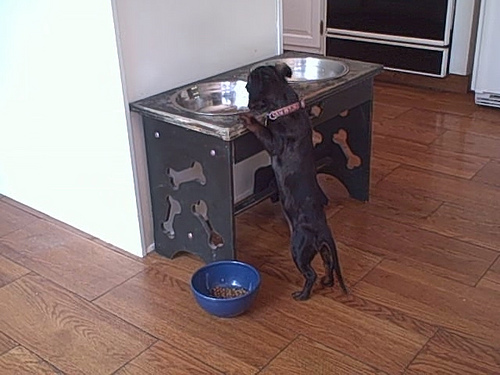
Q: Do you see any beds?
A: No, there are no beds.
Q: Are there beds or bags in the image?
A: No, there are no beds or bags.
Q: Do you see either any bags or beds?
A: No, there are no beds or bags.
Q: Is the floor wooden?
A: Yes, the floor is wooden.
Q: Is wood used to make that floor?
A: Yes, the floor is made of wood.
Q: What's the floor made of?
A: The floor is made of wood.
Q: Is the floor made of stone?
A: No, the floor is made of wood.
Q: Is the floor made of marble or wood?
A: The floor is made of wood.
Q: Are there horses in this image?
A: No, there are no horses.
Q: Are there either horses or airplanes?
A: No, there are no horses or airplanes.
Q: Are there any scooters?
A: No, there are no scooters.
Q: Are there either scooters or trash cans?
A: No, there are no scooters or trash cans.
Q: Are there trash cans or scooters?
A: No, there are no scooters or trash cans.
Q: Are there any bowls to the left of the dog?
A: Yes, there is a bowl to the left of the dog.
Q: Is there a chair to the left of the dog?
A: No, there is a bowl to the left of the dog.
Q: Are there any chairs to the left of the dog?
A: No, there is a bowl to the left of the dog.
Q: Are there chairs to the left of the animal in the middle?
A: No, there is a bowl to the left of the dog.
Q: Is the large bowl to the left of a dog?
A: Yes, the bowl is to the left of a dog.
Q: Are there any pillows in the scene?
A: No, there are no pillows.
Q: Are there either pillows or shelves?
A: No, there are no pillows or shelves.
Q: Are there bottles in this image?
A: No, there are no bottles.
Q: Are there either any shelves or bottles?
A: No, there are no bottles or shelves.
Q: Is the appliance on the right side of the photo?
A: Yes, the appliance is on the right of the image.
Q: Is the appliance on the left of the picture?
A: No, the appliance is on the right of the image.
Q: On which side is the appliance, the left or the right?
A: The appliance is on the right of the image.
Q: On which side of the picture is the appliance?
A: The appliance is on the right of the image.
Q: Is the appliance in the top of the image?
A: Yes, the appliance is in the top of the image.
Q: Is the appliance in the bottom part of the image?
A: No, the appliance is in the top of the image.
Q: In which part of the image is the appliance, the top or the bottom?
A: The appliance is in the top of the image.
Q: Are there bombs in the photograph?
A: No, there are no bombs.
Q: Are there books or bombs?
A: No, there are no bombs or books.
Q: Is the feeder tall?
A: Yes, the feeder is tall.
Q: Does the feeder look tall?
A: Yes, the feeder is tall.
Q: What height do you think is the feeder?
A: The feeder is tall.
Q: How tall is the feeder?
A: The feeder is tall.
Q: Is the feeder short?
A: No, the feeder is tall.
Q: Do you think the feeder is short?
A: No, the feeder is tall.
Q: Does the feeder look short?
A: No, the feeder is tall.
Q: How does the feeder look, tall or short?
A: The feeder is tall.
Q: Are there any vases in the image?
A: No, there are no vases.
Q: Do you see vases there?
A: No, there are no vases.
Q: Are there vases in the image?
A: No, there are no vases.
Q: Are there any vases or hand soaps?
A: No, there are no vases or hand soaps.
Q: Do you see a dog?
A: Yes, there is a dog.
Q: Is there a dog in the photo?
A: Yes, there is a dog.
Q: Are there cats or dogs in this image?
A: Yes, there is a dog.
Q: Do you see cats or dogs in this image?
A: Yes, there is a dog.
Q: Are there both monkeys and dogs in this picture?
A: No, there is a dog but no monkeys.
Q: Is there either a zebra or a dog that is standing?
A: Yes, the dog is standing.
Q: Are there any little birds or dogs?
A: Yes, there is a little dog.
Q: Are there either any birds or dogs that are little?
A: Yes, the dog is little.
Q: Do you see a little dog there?
A: Yes, there is a little dog.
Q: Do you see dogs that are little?
A: Yes, there is a little dog.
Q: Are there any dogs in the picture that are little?
A: Yes, there is a dog that is little.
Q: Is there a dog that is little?
A: Yes, there is a dog that is little.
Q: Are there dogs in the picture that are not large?
A: Yes, there is a little dog.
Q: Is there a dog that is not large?
A: Yes, there is a little dog.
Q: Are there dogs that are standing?
A: Yes, there is a dog that is standing.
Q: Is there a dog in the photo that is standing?
A: Yes, there is a dog that is standing.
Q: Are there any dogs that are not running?
A: Yes, there is a dog that is standing.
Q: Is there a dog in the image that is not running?
A: Yes, there is a dog that is standing.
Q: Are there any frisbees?
A: No, there are no frisbees.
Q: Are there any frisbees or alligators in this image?
A: No, there are no frisbees or alligators.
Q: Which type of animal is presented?
A: The animal is a dog.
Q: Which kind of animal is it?
A: The animal is a dog.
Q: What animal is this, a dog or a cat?
A: That is a dog.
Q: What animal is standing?
A: The animal is a dog.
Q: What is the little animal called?
A: The animal is a dog.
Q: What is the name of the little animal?
A: The animal is a dog.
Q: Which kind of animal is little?
A: The animal is a dog.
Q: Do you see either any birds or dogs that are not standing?
A: No, there is a dog but it is standing.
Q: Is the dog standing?
A: Yes, the dog is standing.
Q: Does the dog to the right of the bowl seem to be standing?
A: Yes, the dog is standing.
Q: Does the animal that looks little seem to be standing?
A: Yes, the dog is standing.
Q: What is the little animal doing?
A: The dog is standing.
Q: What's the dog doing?
A: The dog is standing.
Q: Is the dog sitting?
A: No, the dog is standing.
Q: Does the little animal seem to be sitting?
A: No, the dog is standing.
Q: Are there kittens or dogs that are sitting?
A: No, there is a dog but it is standing.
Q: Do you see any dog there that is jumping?
A: No, there is a dog but it is standing.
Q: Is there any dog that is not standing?
A: No, there is a dog but it is standing.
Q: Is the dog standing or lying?
A: The dog is standing.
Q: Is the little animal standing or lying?
A: The dog is standing.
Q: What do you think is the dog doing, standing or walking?
A: The dog is standing.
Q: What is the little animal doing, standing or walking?
A: The dog is standing.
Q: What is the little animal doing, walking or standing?
A: The dog is standing.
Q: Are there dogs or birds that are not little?
A: No, there is a dog but it is little.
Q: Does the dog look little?
A: Yes, the dog is little.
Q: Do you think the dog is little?
A: Yes, the dog is little.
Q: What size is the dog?
A: The dog is little.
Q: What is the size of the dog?
A: The dog is little.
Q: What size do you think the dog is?
A: The dog is little.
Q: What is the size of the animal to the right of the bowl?
A: The dog is little.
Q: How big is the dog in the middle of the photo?
A: The dog is little.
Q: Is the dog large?
A: No, the dog is little.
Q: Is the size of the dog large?
A: No, the dog is little.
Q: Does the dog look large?
A: No, the dog is little.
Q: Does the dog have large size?
A: No, the dog is little.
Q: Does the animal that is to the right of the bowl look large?
A: No, the dog is little.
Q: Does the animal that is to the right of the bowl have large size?
A: No, the dog is little.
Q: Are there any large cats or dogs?
A: No, there is a dog but it is little.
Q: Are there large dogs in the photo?
A: No, there is a dog but it is little.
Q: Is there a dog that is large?
A: No, there is a dog but it is little.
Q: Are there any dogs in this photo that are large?
A: No, there is a dog but it is little.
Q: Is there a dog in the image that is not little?
A: No, there is a dog but it is little.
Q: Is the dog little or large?
A: The dog is little.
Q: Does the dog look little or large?
A: The dog is little.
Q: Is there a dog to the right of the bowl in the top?
A: Yes, there is a dog to the right of the bowl.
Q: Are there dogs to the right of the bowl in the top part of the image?
A: Yes, there is a dog to the right of the bowl.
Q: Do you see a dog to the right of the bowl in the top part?
A: Yes, there is a dog to the right of the bowl.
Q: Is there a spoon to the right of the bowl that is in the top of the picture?
A: No, there is a dog to the right of the bowl.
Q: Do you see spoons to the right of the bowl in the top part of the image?
A: No, there is a dog to the right of the bowl.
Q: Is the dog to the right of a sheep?
A: No, the dog is to the right of the bowl.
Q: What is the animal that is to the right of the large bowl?
A: The animal is a dog.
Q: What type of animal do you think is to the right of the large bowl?
A: The animal is a dog.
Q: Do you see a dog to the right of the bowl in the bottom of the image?
A: Yes, there is a dog to the right of the bowl.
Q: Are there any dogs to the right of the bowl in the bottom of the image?
A: Yes, there is a dog to the right of the bowl.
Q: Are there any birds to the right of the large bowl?
A: No, there is a dog to the right of the bowl.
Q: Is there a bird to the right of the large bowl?
A: No, there is a dog to the right of the bowl.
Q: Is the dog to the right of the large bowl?
A: Yes, the dog is to the right of the bowl.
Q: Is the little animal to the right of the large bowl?
A: Yes, the dog is to the right of the bowl.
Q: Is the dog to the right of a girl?
A: No, the dog is to the right of the bowl.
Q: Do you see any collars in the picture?
A: Yes, there is a collar.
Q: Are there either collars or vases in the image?
A: Yes, there is a collar.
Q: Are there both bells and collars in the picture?
A: No, there is a collar but no bells.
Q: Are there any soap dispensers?
A: No, there are no soap dispensers.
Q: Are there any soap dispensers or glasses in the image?
A: No, there are no soap dispensers or glasses.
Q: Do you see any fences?
A: No, there are no fences.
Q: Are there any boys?
A: No, there are no boys.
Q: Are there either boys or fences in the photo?
A: No, there are no boys or fences.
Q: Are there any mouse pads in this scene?
A: No, there are no mouse pads.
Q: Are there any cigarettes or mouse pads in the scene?
A: No, there are no mouse pads or cigarettes.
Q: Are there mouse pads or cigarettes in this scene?
A: No, there are no mouse pads or cigarettes.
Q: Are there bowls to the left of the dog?
A: Yes, there is a bowl to the left of the dog.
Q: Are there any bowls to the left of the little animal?
A: Yes, there is a bowl to the left of the dog.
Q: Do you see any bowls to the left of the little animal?
A: Yes, there is a bowl to the left of the dog.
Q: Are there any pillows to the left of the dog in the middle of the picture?
A: No, there is a bowl to the left of the dog.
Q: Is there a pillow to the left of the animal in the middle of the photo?
A: No, there is a bowl to the left of the dog.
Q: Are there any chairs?
A: No, there are no chairs.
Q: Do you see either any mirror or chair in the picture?
A: No, there are no chairs or mirrors.